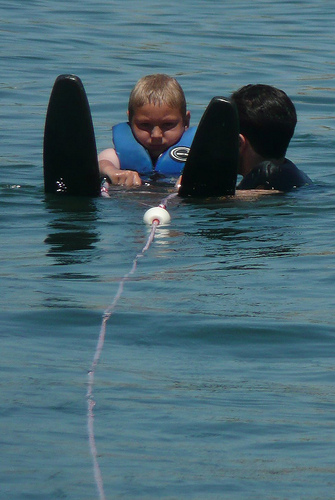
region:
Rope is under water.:
[85, 247, 147, 447]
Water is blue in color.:
[117, 391, 218, 489]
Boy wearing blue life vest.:
[111, 107, 237, 214]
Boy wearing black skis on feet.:
[34, 98, 270, 190]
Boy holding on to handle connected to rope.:
[113, 165, 197, 230]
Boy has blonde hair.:
[93, 52, 218, 129]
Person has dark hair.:
[237, 87, 284, 128]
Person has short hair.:
[245, 92, 293, 165]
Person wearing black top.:
[248, 156, 299, 189]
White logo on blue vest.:
[171, 142, 195, 169]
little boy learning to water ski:
[47, 71, 236, 204]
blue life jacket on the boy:
[110, 122, 198, 181]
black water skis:
[43, 75, 235, 199]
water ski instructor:
[230, 88, 315, 188]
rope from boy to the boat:
[86, 180, 181, 498]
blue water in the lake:
[2, 4, 333, 498]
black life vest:
[240, 162, 318, 192]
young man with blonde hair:
[98, 75, 196, 194]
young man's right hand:
[98, 159, 142, 187]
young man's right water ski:
[42, 73, 101, 196]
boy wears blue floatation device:
[107, 120, 207, 189]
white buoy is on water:
[129, 200, 176, 229]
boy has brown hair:
[115, 78, 187, 116]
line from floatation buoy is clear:
[85, 193, 173, 493]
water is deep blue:
[7, 174, 319, 482]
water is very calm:
[14, 176, 310, 484]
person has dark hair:
[224, 86, 303, 211]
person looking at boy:
[220, 77, 320, 199]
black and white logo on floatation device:
[166, 145, 204, 164]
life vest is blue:
[111, 113, 205, 186]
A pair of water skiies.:
[35, 71, 247, 208]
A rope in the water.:
[48, 218, 142, 498]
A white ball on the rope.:
[141, 206, 172, 230]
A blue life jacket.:
[111, 118, 201, 197]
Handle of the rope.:
[100, 171, 183, 196]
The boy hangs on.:
[113, 168, 142, 189]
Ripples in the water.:
[193, 218, 306, 271]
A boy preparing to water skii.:
[39, 70, 244, 215]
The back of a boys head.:
[223, 62, 298, 161]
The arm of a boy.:
[95, 140, 142, 196]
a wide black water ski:
[44, 71, 102, 195]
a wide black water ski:
[180, 93, 237, 201]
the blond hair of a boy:
[126, 73, 184, 114]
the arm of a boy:
[97, 145, 140, 184]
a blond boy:
[96, 73, 210, 191]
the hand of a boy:
[109, 169, 140, 185]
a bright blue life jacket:
[111, 118, 209, 180]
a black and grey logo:
[170, 145, 192, 161]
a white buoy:
[145, 205, 172, 227]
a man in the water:
[220, 84, 310, 192]